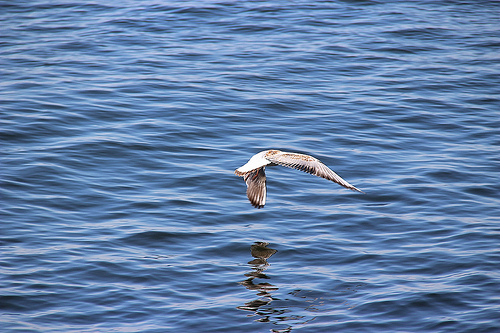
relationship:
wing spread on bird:
[264, 143, 377, 198] [232, 149, 366, 210]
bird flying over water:
[206, 113, 371, 222] [1, 1, 499, 332]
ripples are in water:
[368, 18, 429, 105] [7, 8, 491, 330]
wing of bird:
[264, 148, 366, 195] [238, 126, 368, 193]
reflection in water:
[236, 237, 306, 331] [7, 8, 491, 330]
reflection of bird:
[236, 237, 306, 331] [232, 149, 366, 210]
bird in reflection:
[232, 149, 366, 210] [236, 237, 306, 331]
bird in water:
[232, 149, 366, 210] [7, 8, 491, 330]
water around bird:
[7, 8, 491, 330] [232, 149, 366, 210]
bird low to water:
[232, 149, 366, 210] [7, 8, 491, 330]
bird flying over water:
[232, 149, 366, 210] [193, 196, 371, 252]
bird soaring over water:
[232, 149, 366, 210] [182, 198, 380, 261]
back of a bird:
[256, 150, 272, 162] [233, 141, 366, 208]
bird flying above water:
[232, 149, 366, 210] [7, 8, 491, 330]